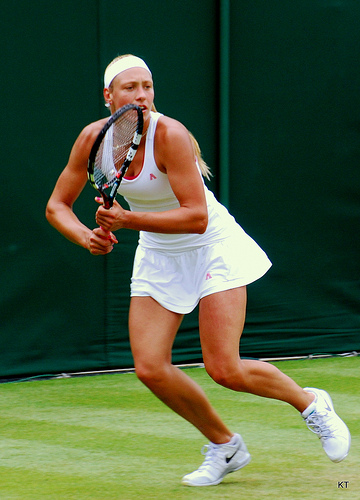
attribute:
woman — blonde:
[41, 50, 355, 488]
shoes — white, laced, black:
[169, 387, 357, 493]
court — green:
[2, 354, 359, 499]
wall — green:
[1, 1, 359, 367]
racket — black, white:
[77, 101, 145, 254]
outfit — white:
[89, 112, 279, 318]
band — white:
[101, 53, 159, 87]